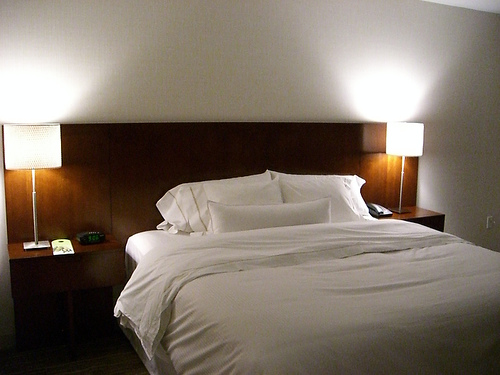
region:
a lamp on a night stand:
[0, 124, 65, 266]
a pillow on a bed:
[198, 189, 333, 233]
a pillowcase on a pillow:
[161, 166, 266, 235]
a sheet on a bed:
[107, 195, 463, 315]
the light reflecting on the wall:
[350, 71, 429, 121]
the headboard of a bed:
[6, 119, 421, 223]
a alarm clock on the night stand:
[78, 227, 103, 258]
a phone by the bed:
[367, 198, 388, 218]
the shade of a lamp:
[1, 131, 66, 176]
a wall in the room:
[275, 0, 374, 89]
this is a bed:
[161, 222, 443, 373]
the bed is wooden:
[85, 130, 143, 188]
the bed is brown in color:
[91, 144, 137, 187]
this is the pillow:
[210, 200, 326, 221]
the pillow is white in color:
[226, 207, 276, 222]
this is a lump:
[4, 126, 68, 166]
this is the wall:
[58, 11, 398, 108]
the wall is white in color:
[87, 22, 290, 86]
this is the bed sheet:
[231, 282, 342, 342]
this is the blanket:
[180, 226, 344, 266]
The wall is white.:
[174, 7, 308, 102]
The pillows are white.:
[153, 152, 380, 239]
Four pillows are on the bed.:
[152, 152, 367, 257]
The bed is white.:
[201, 251, 397, 370]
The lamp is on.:
[1, 120, 70, 262]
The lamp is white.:
[1, 114, 71, 264]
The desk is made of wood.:
[2, 222, 143, 368]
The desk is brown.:
[2, 228, 142, 370]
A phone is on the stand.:
[358, 186, 403, 236]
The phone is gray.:
[352, 192, 397, 229]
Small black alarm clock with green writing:
[71, 225, 113, 253]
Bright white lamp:
[0, 112, 55, 247]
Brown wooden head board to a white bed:
[103, 108, 363, 223]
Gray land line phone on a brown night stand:
[365, 192, 393, 227]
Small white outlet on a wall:
[482, 205, 499, 234]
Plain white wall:
[115, 22, 390, 97]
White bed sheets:
[224, 250, 420, 330]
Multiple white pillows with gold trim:
[167, 153, 345, 232]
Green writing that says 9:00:
[83, 230, 104, 245]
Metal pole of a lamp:
[383, 148, 413, 208]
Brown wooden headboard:
[4, 108, 425, 210]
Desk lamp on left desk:
[3, 116, 63, 249]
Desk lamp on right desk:
[378, 113, 425, 215]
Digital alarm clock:
[72, 224, 106, 249]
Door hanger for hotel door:
[43, 232, 76, 259]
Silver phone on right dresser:
[363, 196, 393, 221]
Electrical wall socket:
[484, 214, 496, 234]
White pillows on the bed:
[146, 158, 378, 236]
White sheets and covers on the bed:
[119, 219, 497, 369]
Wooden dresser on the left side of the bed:
[3, 223, 135, 371]